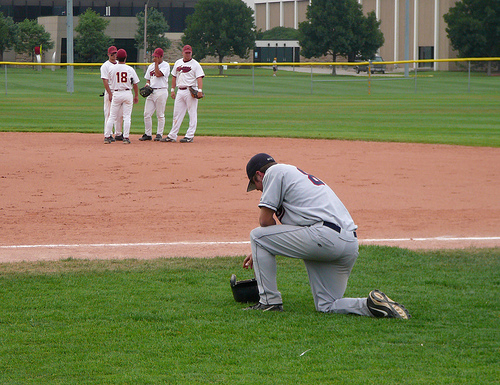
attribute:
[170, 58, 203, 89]
jersey — white in color, white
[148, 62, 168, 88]
jersey — white colored, white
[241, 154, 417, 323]
baseball player — kneeling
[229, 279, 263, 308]
baseball glove — black, mitt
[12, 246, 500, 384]
grass — green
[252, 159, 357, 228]
uniform — white colored, gray, white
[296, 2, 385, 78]
tree — brown, green colored, colored green, green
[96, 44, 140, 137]
baseball player — standing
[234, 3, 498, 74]
building — brown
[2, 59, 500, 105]
fence — yellow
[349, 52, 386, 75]
van — gray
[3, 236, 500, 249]
line — white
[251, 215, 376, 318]
pants — white colored, white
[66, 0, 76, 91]
pole — silver, tall